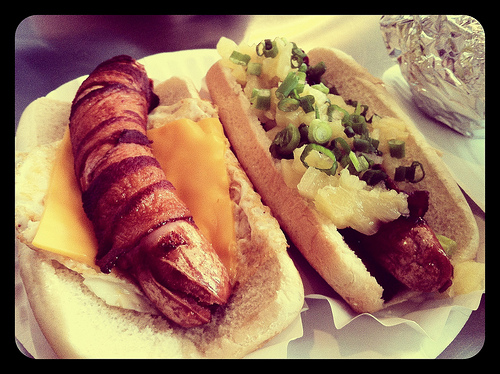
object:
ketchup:
[374, 212, 455, 290]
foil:
[380, 15, 485, 140]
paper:
[246, 297, 485, 359]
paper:
[382, 44, 486, 216]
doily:
[286, 242, 486, 334]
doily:
[14, 247, 313, 358]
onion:
[214, 37, 250, 66]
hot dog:
[363, 210, 451, 291]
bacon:
[66, 56, 230, 330]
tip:
[404, 260, 454, 294]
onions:
[296, 159, 416, 233]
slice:
[310, 117, 335, 146]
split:
[148, 255, 226, 325]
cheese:
[28, 114, 238, 281]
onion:
[301, 55, 328, 82]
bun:
[6, 79, 304, 359]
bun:
[196, 48, 478, 314]